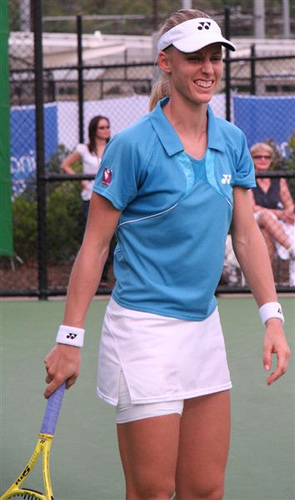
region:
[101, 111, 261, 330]
The woman has a blue shirt on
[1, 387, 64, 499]
The tennis racket is yellow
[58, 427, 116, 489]
The court floor is green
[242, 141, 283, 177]
The person has sunglasses on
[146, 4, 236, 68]
The woman is wearing a visor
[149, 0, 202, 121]
The woman's hair is pulled back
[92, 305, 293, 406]
The woman has a skirt on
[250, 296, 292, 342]
The wrist guards are white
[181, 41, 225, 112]
She is making a funny face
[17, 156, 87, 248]
The bushes are green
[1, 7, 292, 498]
Woman holding a tennis racket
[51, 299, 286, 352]
White wristbands on a wan's wrists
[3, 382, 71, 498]
Yellow tennis racket with purple handle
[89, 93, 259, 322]
Blue collared shirt on a woman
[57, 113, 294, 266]
Two women watching a tennis game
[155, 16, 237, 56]
White sun visor on a woman's head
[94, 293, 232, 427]
White skirt with spandex shorts underneath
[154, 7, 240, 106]
A woman smiling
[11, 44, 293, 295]
A tall chain link fence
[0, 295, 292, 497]
Green ground on tennis court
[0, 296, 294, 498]
a tennis court surface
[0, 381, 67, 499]
a tennis racket held by the player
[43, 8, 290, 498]
a female tennis player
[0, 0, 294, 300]
a black chain link fence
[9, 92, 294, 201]
a blue and white banner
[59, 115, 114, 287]
a spectator behind the fence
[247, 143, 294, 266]
a spectator behind the fence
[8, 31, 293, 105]
a white building in the background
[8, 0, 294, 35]
a group of green trees in the background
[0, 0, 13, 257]
a green object on the fence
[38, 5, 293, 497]
A woman in the foreground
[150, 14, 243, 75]
Woman is wearing a cap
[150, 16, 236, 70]
The cap is white in color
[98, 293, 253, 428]
Woman is wearing a skirt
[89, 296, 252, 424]
The skirt is white in color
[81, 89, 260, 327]
Woman is wearing a blue polo shirt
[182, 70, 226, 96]
Woman in the foreground is smiling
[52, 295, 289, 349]
Woman is wearing white wristbands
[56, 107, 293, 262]
People in the background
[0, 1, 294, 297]
A black chain link fence in the background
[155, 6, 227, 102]
a smiling woman in a cap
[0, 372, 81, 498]
a yellow tennis racket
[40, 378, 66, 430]
a purple grip to a tennis racket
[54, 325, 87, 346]
a white and black wristband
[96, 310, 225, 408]
a pair of white athletic shorts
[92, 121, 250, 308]
a bright blue shirt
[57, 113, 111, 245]
an onlooker dressed in white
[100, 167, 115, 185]
a red logo on a shirt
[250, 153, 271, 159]
a pair of dark sunglasses